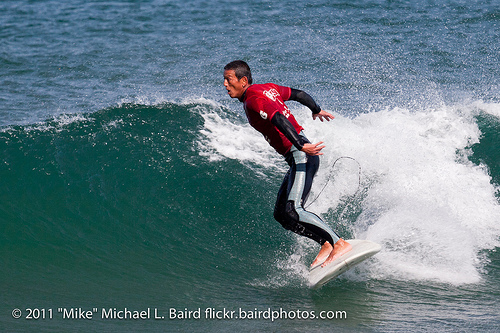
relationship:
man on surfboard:
[220, 61, 351, 270] [306, 238, 383, 291]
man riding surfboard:
[220, 61, 351, 270] [306, 238, 383, 291]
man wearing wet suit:
[220, 61, 351, 270] [239, 83, 342, 244]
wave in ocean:
[3, 96, 499, 290] [1, 1, 498, 329]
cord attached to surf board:
[304, 156, 362, 232] [309, 237, 384, 286]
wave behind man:
[3, 96, 499, 290] [220, 61, 351, 270]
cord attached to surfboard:
[305, 157, 356, 226] [306, 238, 383, 291]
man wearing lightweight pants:
[220, 61, 351, 270] [273, 149, 339, 246]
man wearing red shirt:
[220, 61, 351, 270] [240, 84, 304, 157]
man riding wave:
[220, 61, 351, 270] [3, 96, 499, 290]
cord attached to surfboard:
[304, 156, 362, 232] [306, 238, 383, 291]